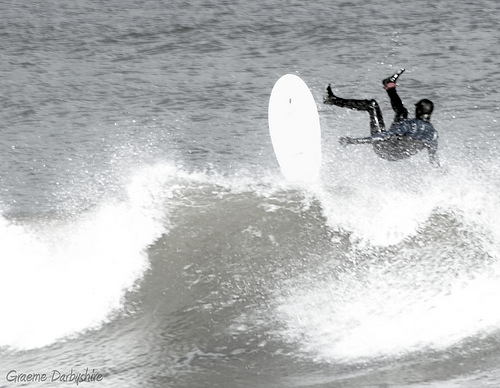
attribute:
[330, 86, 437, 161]
wet suit — black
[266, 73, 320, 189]
surfboard — painted white, perpendicular, white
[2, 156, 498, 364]
wave — in water, breaking, white, foamy, large, spraying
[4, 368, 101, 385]
phographer's name — here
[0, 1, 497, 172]
waves — grey, small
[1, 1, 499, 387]
water — moving, spraying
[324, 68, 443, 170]
person — being thrown, wiping out, in air, flying, falling, wet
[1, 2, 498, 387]
ocean — swelling